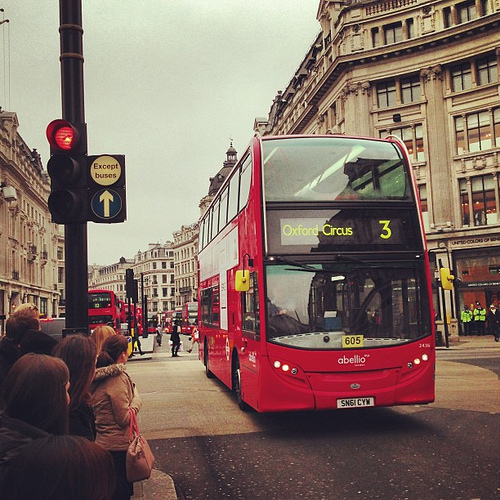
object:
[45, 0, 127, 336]
bus stop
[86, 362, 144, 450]
jacket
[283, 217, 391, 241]
words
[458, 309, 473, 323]
coat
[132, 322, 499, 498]
road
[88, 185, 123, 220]
sign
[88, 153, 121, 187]
sign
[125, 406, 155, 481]
purse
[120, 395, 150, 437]
handles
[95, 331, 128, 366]
head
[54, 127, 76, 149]
light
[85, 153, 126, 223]
sign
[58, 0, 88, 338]
pole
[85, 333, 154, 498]
person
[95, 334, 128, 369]
hair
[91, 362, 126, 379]
fur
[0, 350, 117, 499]
person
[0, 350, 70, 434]
hair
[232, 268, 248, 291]
mirror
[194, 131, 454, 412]
bus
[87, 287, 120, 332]
buses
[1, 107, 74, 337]
building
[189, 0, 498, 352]
building